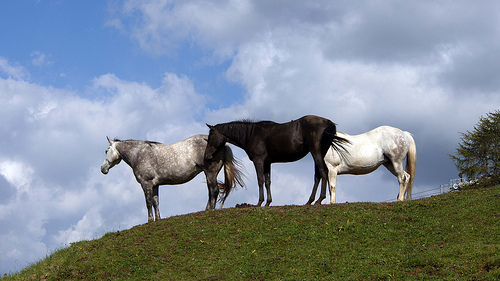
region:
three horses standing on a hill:
[94, 115, 494, 222]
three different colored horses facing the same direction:
[75, 113, 422, 221]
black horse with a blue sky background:
[201, 101, 340, 209]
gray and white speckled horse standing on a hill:
[92, 125, 206, 249]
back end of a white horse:
[360, 116, 422, 203]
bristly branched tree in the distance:
[429, 90, 499, 202]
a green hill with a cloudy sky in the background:
[5, 212, 283, 278]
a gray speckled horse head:
[90, 132, 154, 179]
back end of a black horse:
[291, 107, 333, 207]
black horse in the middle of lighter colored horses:
[71, 71, 432, 216]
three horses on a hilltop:
[60, 96, 445, 237]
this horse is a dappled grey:
[97, 117, 238, 225]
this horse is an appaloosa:
[326, 100, 442, 202]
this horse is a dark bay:
[188, 105, 365, 212]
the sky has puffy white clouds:
[29, 50, 151, 131]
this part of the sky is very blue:
[41, 11, 101, 58]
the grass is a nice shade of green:
[219, 220, 331, 271]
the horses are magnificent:
[60, 62, 483, 257]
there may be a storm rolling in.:
[347, 8, 479, 99]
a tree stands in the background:
[445, 101, 495, 208]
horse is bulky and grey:
[81, 117, 237, 229]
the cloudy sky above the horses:
[3, 4, 498, 246]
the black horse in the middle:
[196, 115, 331, 204]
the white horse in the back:
[318, 120, 421, 212]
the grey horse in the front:
[98, 130, 235, 225]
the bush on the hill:
[446, 105, 499, 175]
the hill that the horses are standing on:
[4, 185, 498, 280]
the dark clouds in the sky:
[312, 5, 492, 191]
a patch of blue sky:
[4, 0, 138, 89]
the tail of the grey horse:
[212, 147, 245, 205]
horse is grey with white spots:
[73, 117, 233, 222]